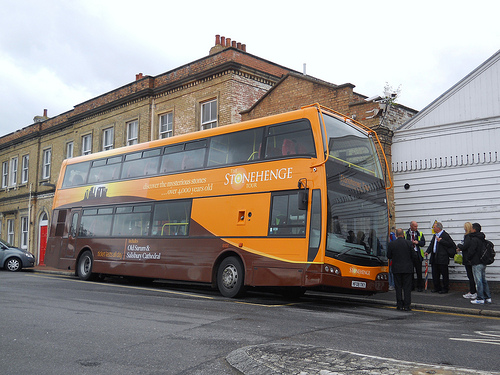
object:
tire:
[269, 277, 310, 299]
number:
[351, 281, 368, 288]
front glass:
[322, 108, 391, 267]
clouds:
[0, 62, 113, 92]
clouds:
[337, 0, 498, 53]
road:
[253, 300, 498, 343]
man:
[423, 220, 451, 293]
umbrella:
[422, 253, 429, 293]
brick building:
[0, 33, 395, 265]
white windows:
[198, 97, 221, 131]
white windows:
[154, 108, 175, 140]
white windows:
[125, 116, 139, 145]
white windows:
[100, 126, 115, 151]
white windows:
[80, 130, 94, 156]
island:
[226, 341, 500, 374]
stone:
[36, 100, 396, 298]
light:
[324, 264, 341, 276]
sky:
[286, 0, 498, 55]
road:
[1, 288, 220, 373]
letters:
[224, 167, 294, 188]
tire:
[76, 248, 93, 280]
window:
[262, 118, 317, 159]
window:
[206, 127, 266, 167]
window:
[158, 136, 207, 173]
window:
[119, 148, 160, 180]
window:
[60, 160, 91, 189]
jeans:
[472, 264, 493, 300]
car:
[0, 239, 36, 272]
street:
[0, 292, 497, 373]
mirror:
[297, 190, 309, 211]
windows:
[87, 155, 123, 183]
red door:
[39, 225, 48, 266]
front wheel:
[216, 255, 244, 297]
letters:
[141, 167, 293, 197]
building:
[390, 46, 499, 284]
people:
[386, 228, 417, 310]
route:
[338, 171, 378, 197]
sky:
[48, 19, 129, 36]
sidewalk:
[393, 282, 500, 309]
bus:
[42, 103, 393, 298]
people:
[401, 219, 427, 292]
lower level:
[43, 188, 395, 298]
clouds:
[0, 7, 105, 43]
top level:
[53, 102, 394, 192]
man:
[463, 222, 496, 305]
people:
[455, 220, 476, 300]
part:
[58, 103, 323, 182]